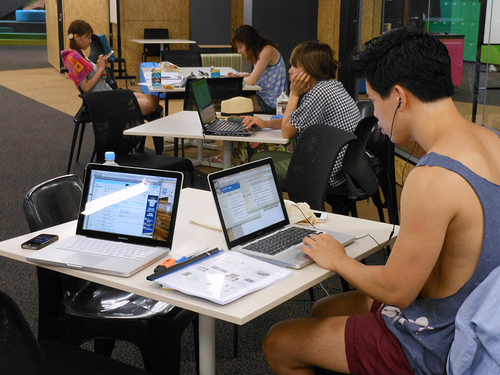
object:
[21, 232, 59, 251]
phone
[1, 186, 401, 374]
table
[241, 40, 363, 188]
person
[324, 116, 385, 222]
chair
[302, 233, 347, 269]
hand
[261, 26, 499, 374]
person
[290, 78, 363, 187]
shirt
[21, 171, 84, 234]
part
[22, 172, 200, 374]
chair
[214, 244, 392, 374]
part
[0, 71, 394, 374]
carpet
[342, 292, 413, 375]
shorts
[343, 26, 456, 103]
hair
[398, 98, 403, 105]
earphone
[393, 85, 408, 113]
ear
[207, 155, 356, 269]
laptop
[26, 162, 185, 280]
laptop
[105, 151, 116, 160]
cap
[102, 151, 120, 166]
bottle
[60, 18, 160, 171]
woman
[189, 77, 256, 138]
laptop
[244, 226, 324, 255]
keys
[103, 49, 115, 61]
phone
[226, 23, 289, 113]
person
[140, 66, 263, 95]
table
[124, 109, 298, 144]
table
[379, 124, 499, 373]
shirt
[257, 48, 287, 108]
shirt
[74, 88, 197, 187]
chair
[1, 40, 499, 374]
floor